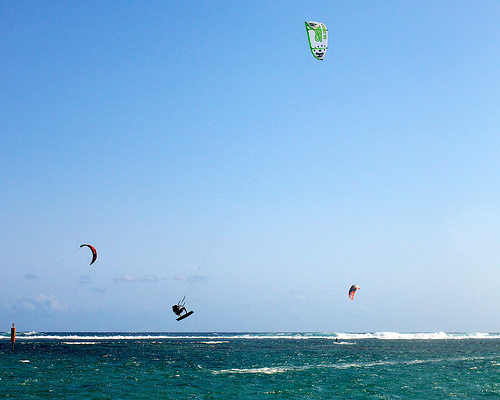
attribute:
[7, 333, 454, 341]
foam — white 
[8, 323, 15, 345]
post — orange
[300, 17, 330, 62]
sail — white, green, black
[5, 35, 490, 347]
skies — clear, blue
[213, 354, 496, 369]
foam — white 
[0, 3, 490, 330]
sky — blue, clear, bright 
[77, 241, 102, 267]
parasail — red, black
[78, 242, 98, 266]
kite — folded-over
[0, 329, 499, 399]
waters — blue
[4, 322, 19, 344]
floater — orange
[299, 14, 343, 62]
kite — green, white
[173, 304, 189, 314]
vest — black 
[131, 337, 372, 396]
ocean — blue, aqua